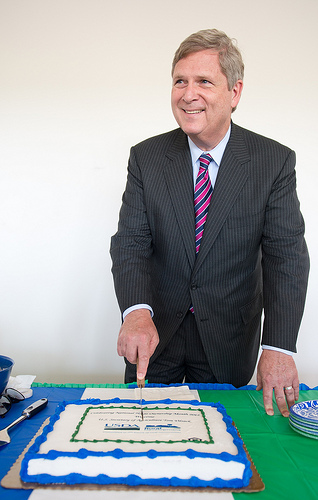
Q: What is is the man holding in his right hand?
A: Knife.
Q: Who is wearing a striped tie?
A: The man.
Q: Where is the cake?
A: On the table.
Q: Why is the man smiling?
A: He is happy.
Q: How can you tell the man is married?
A: Ring on 4th finger left hand.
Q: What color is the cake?
A: Blue and white.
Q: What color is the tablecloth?
A: Green.